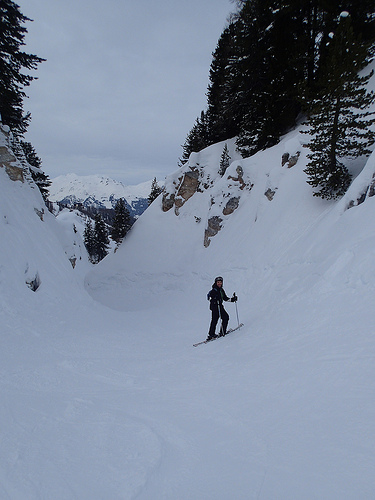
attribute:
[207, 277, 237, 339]
person — skiing, standing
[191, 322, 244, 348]
skis — a pair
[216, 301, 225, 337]
ski pole — long, metal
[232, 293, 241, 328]
ski pole — long, metal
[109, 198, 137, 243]
evergreen tree — in background, far, medium sized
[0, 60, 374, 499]
snow — white, thick, large patch, cold, icy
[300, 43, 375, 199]
evergreen tree — small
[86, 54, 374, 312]
hill — tall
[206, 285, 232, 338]
clothing — black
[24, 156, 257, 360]
gulley — snow covered, of snow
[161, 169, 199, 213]
rock — large, brown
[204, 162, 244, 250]
rock — large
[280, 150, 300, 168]
rock — large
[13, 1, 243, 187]
sky — gray, white, cloudy, overcast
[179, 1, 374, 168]
pine trees — tall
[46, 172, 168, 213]
mountains — in distance, snow covered, snow capped, in background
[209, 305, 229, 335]
snow pants — black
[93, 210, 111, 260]
evergreen tree — far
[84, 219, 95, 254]
evergreen tree — far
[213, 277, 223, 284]
hat — black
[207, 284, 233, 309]
coat — black